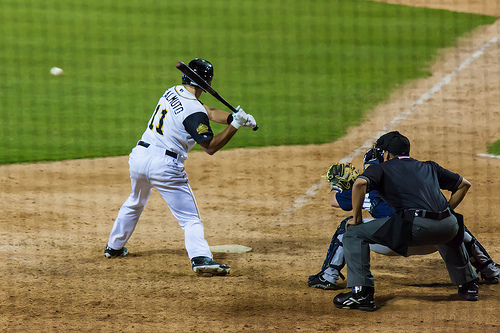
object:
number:
[147, 103, 167, 135]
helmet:
[182, 57, 214, 93]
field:
[15, 8, 487, 315]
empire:
[332, 123, 481, 314]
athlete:
[101, 56, 258, 277]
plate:
[209, 244, 254, 255]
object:
[204, 241, 250, 254]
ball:
[50, 66, 64, 76]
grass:
[0, 92, 103, 154]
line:
[418, 51, 485, 101]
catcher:
[303, 160, 498, 291]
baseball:
[36, 45, 90, 89]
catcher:
[330, 128, 482, 313]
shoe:
[102, 243, 128, 259]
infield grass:
[15, 9, 448, 122]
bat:
[173, 54, 264, 133]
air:
[34, 48, 80, 92]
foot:
[100, 242, 130, 260]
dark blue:
[343, 155, 467, 287]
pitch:
[34, 23, 269, 287]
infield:
[10, 8, 497, 141]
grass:
[281, 28, 373, 84]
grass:
[15, 10, 69, 47]